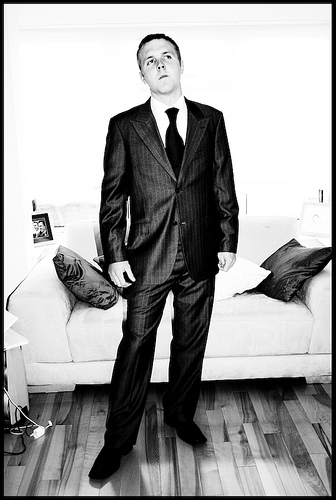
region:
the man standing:
[88, 33, 237, 481]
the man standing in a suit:
[86, 26, 241, 481]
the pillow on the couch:
[52, 241, 117, 306]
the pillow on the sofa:
[254, 238, 334, 291]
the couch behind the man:
[20, 216, 334, 383]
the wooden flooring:
[227, 409, 333, 472]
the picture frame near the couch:
[28, 212, 55, 245]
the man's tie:
[163, 108, 187, 172]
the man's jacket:
[97, 96, 241, 285]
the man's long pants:
[105, 233, 216, 442]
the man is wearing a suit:
[82, 16, 249, 430]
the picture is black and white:
[16, 36, 322, 475]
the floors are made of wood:
[43, 403, 304, 487]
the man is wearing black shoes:
[63, 394, 235, 478]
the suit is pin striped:
[61, 95, 264, 450]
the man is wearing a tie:
[115, 26, 195, 173]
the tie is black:
[120, 93, 222, 189]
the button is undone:
[148, 202, 209, 246]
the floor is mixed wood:
[116, 398, 316, 490]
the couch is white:
[20, 216, 318, 375]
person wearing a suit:
[74, 21, 254, 492]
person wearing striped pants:
[102, 224, 228, 459]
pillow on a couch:
[50, 243, 124, 309]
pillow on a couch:
[240, 233, 334, 307]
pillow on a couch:
[197, 244, 272, 309]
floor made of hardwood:
[2, 374, 330, 498]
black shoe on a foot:
[76, 424, 139, 491]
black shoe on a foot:
[155, 403, 209, 448]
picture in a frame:
[27, 209, 53, 248]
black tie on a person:
[160, 100, 188, 174]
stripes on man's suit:
[143, 164, 159, 202]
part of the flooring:
[252, 421, 296, 470]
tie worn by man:
[168, 108, 183, 159]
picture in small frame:
[32, 212, 56, 241]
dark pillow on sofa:
[261, 243, 319, 300]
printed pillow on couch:
[54, 249, 105, 298]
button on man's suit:
[167, 218, 182, 228]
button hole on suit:
[180, 216, 192, 227]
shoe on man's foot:
[177, 426, 207, 445]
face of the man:
[125, 42, 195, 95]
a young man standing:
[88, 33, 239, 483]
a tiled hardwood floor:
[5, 379, 329, 493]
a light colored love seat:
[22, 219, 327, 385]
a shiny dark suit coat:
[95, 97, 237, 289]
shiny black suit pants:
[103, 251, 215, 444]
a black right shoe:
[86, 436, 129, 482]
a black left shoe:
[157, 406, 210, 447]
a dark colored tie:
[161, 104, 185, 180]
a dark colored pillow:
[246, 239, 331, 302]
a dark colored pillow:
[53, 243, 114, 306]